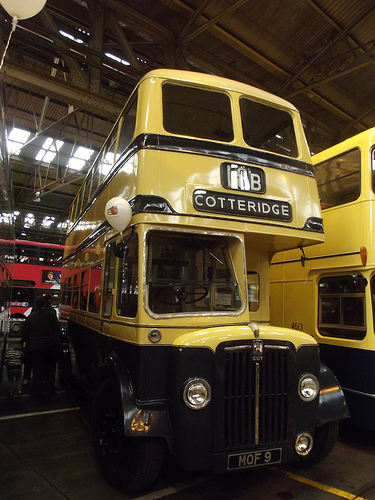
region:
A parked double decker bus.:
[54, 181, 314, 475]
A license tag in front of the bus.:
[231, 433, 289, 479]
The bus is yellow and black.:
[55, 163, 331, 454]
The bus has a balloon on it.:
[87, 192, 142, 248]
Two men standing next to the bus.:
[13, 281, 73, 411]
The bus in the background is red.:
[16, 217, 77, 323]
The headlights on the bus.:
[173, 371, 325, 414]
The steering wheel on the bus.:
[157, 265, 215, 315]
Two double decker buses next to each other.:
[85, 299, 373, 487]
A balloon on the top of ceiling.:
[0, 9, 47, 54]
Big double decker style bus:
[50, 60, 351, 491]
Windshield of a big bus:
[138, 221, 246, 318]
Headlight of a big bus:
[175, 368, 212, 413]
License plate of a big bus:
[219, 442, 286, 472]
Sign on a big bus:
[182, 186, 297, 222]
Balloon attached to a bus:
[97, 190, 134, 246]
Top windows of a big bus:
[154, 71, 306, 163]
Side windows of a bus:
[309, 262, 369, 344]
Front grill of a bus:
[213, 336, 298, 452]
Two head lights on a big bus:
[176, 366, 326, 414]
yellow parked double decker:
[73, 93, 323, 411]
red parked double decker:
[23, 224, 61, 350]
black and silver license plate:
[226, 446, 307, 480]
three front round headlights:
[168, 358, 350, 467]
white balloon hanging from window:
[87, 201, 147, 249]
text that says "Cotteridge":
[199, 179, 305, 220]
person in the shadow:
[24, 291, 80, 398]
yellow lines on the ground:
[310, 475, 356, 494]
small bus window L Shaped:
[114, 215, 247, 331]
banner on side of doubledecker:
[26, 256, 64, 290]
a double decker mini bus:
[122, 63, 322, 492]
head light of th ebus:
[175, 365, 333, 414]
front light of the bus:
[294, 413, 314, 459]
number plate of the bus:
[212, 447, 302, 475]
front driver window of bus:
[147, 231, 276, 322]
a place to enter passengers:
[251, 238, 322, 346]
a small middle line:
[250, 346, 264, 446]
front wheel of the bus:
[84, 404, 148, 491]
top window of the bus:
[146, 81, 304, 150]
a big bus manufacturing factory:
[14, 79, 371, 493]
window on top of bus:
[163, 80, 231, 144]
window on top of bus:
[244, 95, 298, 161]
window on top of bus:
[151, 226, 237, 313]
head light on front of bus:
[185, 372, 211, 411]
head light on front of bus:
[290, 428, 316, 456]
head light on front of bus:
[297, 375, 319, 404]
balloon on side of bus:
[100, 185, 135, 246]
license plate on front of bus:
[227, 445, 280, 471]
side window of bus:
[309, 268, 362, 342]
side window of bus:
[312, 153, 354, 208]